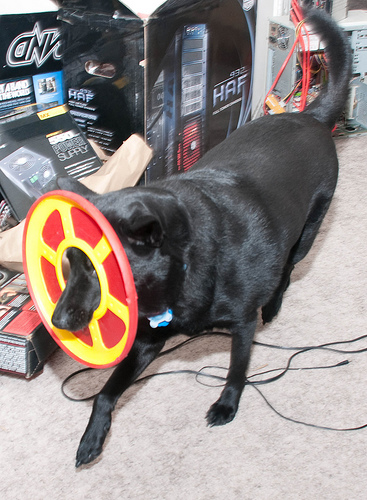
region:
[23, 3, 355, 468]
A black colored dog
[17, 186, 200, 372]
Frisbee on a dog's head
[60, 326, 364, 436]
Black electrical wire on floor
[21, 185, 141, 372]
A yellow and red frisbee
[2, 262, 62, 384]
A box on the floor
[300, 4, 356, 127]
Tail of a dog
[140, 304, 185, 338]
A blue and white collar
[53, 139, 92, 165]
The word "SUPPLY" on a box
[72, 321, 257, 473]
Two legs of a dog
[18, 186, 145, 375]
The frisbee is round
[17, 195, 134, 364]
The red and yellow Frisbee.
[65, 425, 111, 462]
The dog's left paw.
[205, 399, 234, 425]
The dog's right paw.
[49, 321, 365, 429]
The black wires on the floor.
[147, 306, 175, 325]
The blue tag hanging from the dog's collar.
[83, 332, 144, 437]
The front left leg of the dog.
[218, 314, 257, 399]
The front right leg of the dog.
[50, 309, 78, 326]
The nose of the dog.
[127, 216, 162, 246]
The ear of the dog.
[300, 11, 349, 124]
The tail of the dog.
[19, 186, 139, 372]
A round circular object with yellow and red colors.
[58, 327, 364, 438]
A black wire on the floor.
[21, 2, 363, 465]
A black dog with something on his head.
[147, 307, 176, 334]
A blue dog tag.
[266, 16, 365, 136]
A computer system with the case off.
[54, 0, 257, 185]
An open box that is primarily black.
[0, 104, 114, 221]
A power supply box.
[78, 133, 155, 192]
A brown paper bag.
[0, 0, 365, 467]
A dog in the midst of computer equipment.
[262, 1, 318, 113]
Red wires attached to a computer.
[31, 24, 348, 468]
black dog walking on carpet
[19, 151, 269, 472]
black dog with a red and yellow frisbee on head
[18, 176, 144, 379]
red and yellow frisbee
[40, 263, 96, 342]
muzzle of a black dog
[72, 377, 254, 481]
front paws of a black dog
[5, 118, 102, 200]
power supply cord box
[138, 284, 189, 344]
silver and blue collar of a dog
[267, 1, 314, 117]
orange electrical extension cord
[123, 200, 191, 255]
ear of a black dog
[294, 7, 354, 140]
tail of a black dog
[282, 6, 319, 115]
The orange wires behind the dog.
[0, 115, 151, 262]
The brown paper bag on the left.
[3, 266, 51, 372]
The small black box under the brown paper bag.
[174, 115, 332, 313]
The body of the dog.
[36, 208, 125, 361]
The yellow area of the Frisbee.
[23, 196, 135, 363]
The red area of the Frisbee.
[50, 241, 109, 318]
The hole in the center of the Frisbee.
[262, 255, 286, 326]
The back paw of the dog.